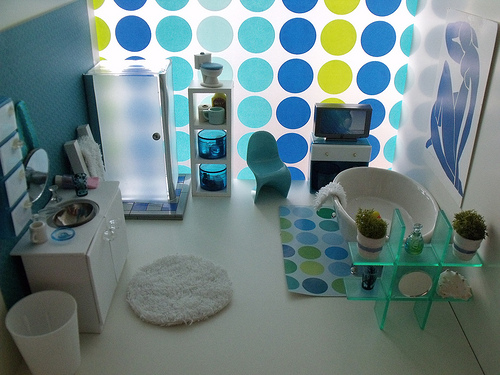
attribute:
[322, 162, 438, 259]
mini bath — white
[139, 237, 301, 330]
rug — white, round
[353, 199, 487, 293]
plants — potted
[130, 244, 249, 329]
rug — small, white, fluffy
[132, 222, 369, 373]
floor — white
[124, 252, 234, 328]
rug — white, small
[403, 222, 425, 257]
vase — green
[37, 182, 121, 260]
sink — silver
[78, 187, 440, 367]
floor — white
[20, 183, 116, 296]
counter — white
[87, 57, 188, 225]
glass shower — small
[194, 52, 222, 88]
toilet — small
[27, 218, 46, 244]
mug — white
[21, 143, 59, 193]
mirror — small, round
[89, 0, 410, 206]
wall — polka-dotted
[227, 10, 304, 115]
glass wall — spotted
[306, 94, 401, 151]
tv — small, black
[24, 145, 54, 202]
mirror — small, circular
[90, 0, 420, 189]
wall — glass, polka-dot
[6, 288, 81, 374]
trash bin — white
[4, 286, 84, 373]
trash can — white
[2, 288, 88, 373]
waste can — white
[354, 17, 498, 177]
portrait — blue and white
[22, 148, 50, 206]
small mirror — circular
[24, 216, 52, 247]
mug — white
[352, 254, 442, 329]
glass shelf — green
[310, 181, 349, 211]
towel — white